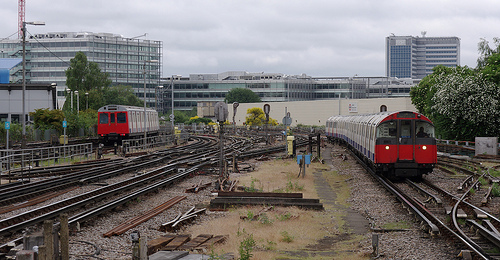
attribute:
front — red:
[95, 105, 128, 138]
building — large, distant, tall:
[385, 35, 460, 77]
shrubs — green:
[33, 108, 99, 141]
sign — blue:
[296, 152, 313, 162]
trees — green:
[410, 37, 500, 144]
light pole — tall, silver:
[22, 20, 48, 134]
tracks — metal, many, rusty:
[0, 123, 313, 259]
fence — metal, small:
[1, 126, 96, 143]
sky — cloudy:
[0, 2, 500, 77]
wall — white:
[228, 96, 424, 128]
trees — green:
[59, 50, 140, 110]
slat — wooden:
[103, 193, 186, 238]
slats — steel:
[210, 189, 322, 206]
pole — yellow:
[285, 135, 296, 156]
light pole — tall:
[142, 57, 161, 150]